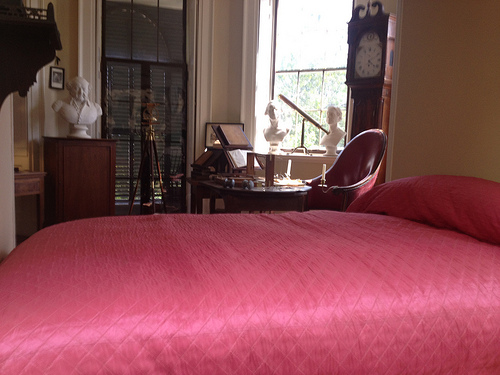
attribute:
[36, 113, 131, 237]
stand — wood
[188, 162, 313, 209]
table — brown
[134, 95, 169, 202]
telescope — brown, gold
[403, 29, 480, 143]
wall — yellow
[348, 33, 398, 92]
clock face — reading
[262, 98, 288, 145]
statute — bathed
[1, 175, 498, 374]
bed — pink, large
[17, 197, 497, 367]
bedspread — hot pink, quilted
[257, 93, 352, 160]
busts — white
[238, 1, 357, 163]
frame — window, drenched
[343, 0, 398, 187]
grandfather clock — brown, tall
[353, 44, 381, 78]
face — white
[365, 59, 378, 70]
hands — black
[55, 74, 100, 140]
statue — white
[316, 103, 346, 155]
bust — white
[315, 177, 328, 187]
candle holder — brass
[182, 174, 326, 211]
table — brown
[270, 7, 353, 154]
window — part 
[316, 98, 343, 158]
statue — head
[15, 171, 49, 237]
nightstand — wooden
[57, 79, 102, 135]
bust — armless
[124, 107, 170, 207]
tripod — gold, black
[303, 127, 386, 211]
chair — dark red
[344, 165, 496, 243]
pillow — red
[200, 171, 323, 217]
table — brown, wooden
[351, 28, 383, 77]
clock face — white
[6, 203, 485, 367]
sheet — red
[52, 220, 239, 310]
design — square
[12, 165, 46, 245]
stand — wooden, short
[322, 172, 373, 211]
arm rest — sloping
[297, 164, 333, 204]
arm rest — sloping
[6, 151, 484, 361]
bed — red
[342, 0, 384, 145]
clock — Brown wooden grandfather 